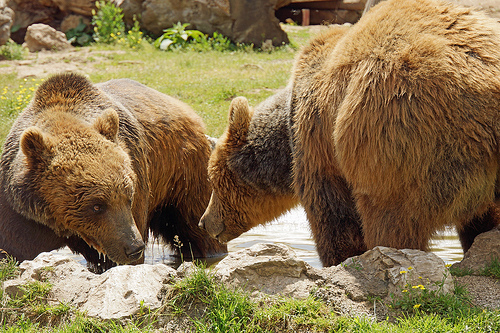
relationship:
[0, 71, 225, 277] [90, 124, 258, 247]
bear facing another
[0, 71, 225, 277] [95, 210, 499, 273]
bear standing in water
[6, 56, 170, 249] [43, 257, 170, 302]
bear near rock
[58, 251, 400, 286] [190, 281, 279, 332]
rocks in grass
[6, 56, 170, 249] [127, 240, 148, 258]
bear has a nose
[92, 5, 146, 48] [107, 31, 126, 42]
plant have yellow flowers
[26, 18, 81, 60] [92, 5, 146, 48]
rock near flowers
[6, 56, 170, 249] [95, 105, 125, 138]
bear straight up ears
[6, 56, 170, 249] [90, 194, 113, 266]
bear looking down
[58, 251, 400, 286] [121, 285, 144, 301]
rocks sharp grey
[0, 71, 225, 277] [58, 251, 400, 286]
bear by rocks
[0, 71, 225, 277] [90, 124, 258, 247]
bear looking eachother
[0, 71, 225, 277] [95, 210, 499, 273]
bear are by water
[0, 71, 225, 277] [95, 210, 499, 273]
bear in water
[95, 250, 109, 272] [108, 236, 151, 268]
water from bears mouth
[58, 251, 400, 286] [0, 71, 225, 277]
rocks next to bear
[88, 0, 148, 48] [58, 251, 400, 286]
flower next to rocks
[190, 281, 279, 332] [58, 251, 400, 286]
grass next rocks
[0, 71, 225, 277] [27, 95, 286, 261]
bear look at each other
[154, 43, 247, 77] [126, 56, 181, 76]
sunlight shines on grass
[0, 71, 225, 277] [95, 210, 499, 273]
bear carefully drinking water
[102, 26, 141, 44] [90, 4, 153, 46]
dandelions growing in weeds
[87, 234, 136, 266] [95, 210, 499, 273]
whiskers from drinking water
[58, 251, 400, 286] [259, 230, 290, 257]
rocks near stream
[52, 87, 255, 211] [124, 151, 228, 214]
friends or enemies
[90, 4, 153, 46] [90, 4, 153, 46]
weeds growing weeds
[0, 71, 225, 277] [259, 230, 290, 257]
bear drinking water from stream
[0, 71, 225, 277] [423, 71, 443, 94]
bear and brown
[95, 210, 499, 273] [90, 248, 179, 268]
water for drinking